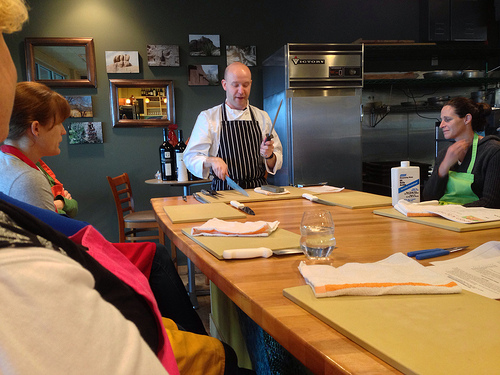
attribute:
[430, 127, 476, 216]
apron — green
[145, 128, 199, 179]
bottles — wine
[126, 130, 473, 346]
table — set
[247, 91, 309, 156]
blade — silver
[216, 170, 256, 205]
knife blade — sharp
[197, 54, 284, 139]
chef — bald, white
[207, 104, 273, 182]
apron — black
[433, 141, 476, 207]
apron — green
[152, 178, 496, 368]
table — long, brown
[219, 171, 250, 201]
knife — long, sharp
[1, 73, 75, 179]
woman — red headed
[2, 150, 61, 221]
shirt — grey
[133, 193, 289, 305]
table — round, wood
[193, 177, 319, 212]
cutting board — long, brown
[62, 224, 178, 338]
apron — pink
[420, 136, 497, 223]
apron — green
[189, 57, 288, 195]
apron — WHITE AND BLACK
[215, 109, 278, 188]
apron — WHITE AND BLACK, STRIPE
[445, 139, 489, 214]
apron — green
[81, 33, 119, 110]
frame — brown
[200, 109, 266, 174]
apron — striped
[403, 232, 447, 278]
handle — blue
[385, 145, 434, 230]
bottle — square, white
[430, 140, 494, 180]
shirt — black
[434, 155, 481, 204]
apron — green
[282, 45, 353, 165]
appliance — large, silver, red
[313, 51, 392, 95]
lights — digital 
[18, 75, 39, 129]
hair — red, pony tail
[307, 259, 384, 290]
towel — closest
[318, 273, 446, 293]
stripe — orange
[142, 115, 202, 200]
bottle — wine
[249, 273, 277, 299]
table — wooden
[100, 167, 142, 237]
chair — brown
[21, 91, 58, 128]
hair — red